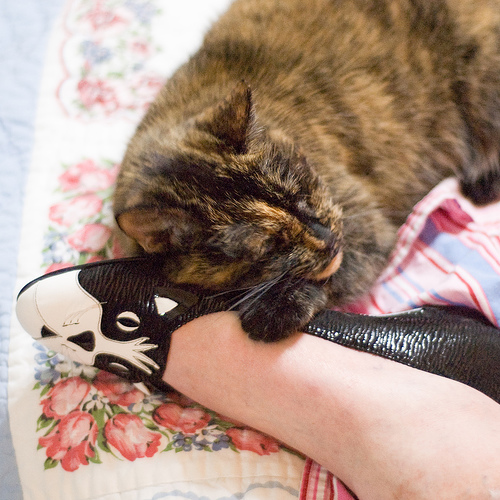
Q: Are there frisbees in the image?
A: No, there are no frisbees.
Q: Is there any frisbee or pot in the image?
A: No, there are no frisbees or pots.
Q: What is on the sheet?
A: The roses are on the sheet.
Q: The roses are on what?
A: The roses are on the bed sheet.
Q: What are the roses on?
A: The roses are on the bed sheet.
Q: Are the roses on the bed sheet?
A: Yes, the roses are on the bed sheet.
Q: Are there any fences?
A: No, there are no fences.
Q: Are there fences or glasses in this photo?
A: No, there are no fences or glasses.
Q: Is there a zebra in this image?
A: No, there are no zebras.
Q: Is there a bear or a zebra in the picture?
A: No, there are no zebras or bears.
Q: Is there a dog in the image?
A: No, there are no dogs.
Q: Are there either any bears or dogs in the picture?
A: No, there are no dogs or bears.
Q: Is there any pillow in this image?
A: No, there are no pillows.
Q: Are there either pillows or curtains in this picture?
A: No, there are no pillows or curtains.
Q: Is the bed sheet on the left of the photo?
A: Yes, the bed sheet is on the left of the image.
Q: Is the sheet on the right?
A: No, the sheet is on the left of the image.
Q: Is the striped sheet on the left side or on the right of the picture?
A: The bed sheet is on the left of the image.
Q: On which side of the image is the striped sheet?
A: The bed sheet is on the left of the image.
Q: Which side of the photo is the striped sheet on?
A: The bed sheet is on the left of the image.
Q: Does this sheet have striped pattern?
A: Yes, the sheet is striped.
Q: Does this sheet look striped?
A: Yes, the sheet is striped.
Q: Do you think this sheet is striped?
A: Yes, the sheet is striped.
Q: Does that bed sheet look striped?
A: Yes, the bed sheet is striped.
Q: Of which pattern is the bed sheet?
A: The bed sheet is striped.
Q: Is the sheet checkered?
A: No, the sheet is striped.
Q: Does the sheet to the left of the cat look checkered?
A: No, the bed sheet is striped.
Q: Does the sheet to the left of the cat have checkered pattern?
A: No, the bed sheet is striped.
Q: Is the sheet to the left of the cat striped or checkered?
A: The bed sheet is striped.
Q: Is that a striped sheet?
A: Yes, that is a striped sheet.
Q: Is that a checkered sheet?
A: No, that is a striped sheet.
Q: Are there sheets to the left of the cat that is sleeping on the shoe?
A: Yes, there is a sheet to the left of the cat.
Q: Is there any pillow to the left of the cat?
A: No, there is a sheet to the left of the cat.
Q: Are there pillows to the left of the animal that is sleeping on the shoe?
A: No, there is a sheet to the left of the cat.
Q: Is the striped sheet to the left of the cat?
A: Yes, the sheet is to the left of the cat.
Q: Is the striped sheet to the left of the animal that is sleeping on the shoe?
A: Yes, the sheet is to the left of the cat.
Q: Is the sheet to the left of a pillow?
A: No, the sheet is to the left of the cat.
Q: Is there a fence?
A: No, there are no fences.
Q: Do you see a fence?
A: No, there are no fences.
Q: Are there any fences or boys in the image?
A: No, there are no fences or boys.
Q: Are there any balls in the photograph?
A: No, there are no balls.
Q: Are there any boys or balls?
A: No, there are no balls or boys.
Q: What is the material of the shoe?
A: The shoe is made of leather.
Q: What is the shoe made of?
A: The shoe is made of leather.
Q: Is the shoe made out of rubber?
A: No, the shoe is made of leather.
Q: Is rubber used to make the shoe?
A: No, the shoe is made of leather.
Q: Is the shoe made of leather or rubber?
A: The shoe is made of leather.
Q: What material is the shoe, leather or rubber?
A: The shoe is made of leather.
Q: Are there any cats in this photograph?
A: Yes, there is a cat.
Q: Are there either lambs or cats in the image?
A: Yes, there is a cat.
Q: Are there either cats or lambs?
A: Yes, there is a cat.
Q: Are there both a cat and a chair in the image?
A: No, there is a cat but no chairs.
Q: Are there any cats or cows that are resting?
A: Yes, the cat is resting.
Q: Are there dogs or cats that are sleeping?
A: Yes, the cat is sleeping.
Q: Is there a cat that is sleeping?
A: Yes, there is a cat that is sleeping.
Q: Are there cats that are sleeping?
A: Yes, there is a cat that is sleeping.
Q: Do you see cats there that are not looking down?
A: Yes, there is a cat that is sleeping .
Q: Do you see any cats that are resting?
A: Yes, there is a cat that is resting.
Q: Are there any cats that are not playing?
A: Yes, there is a cat that is resting.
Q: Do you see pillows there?
A: No, there are no pillows.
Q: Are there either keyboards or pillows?
A: No, there are no pillows or keyboards.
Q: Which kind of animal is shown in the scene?
A: The animal is a cat.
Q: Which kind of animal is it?
A: The animal is a cat.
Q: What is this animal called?
A: That is a cat.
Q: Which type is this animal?
A: That is a cat.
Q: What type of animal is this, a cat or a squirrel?
A: That is a cat.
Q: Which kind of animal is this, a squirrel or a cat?
A: That is a cat.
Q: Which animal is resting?
A: The animal is a cat.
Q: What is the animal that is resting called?
A: The animal is a cat.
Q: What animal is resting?
A: The animal is a cat.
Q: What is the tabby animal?
A: The animal is a cat.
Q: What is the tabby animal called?
A: The animal is a cat.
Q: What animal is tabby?
A: The animal is a cat.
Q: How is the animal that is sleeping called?
A: The animal is a cat.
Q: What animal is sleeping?
A: The animal is a cat.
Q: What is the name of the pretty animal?
A: The animal is a cat.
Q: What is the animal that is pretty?
A: The animal is a cat.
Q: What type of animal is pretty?
A: The animal is a cat.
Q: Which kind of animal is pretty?
A: The animal is a cat.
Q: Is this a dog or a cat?
A: This is a cat.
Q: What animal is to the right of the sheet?
A: The animal is a cat.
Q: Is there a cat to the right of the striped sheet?
A: Yes, there is a cat to the right of the sheet.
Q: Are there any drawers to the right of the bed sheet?
A: No, there is a cat to the right of the bed sheet.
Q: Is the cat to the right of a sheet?
A: Yes, the cat is to the right of a sheet.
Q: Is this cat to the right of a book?
A: No, the cat is to the right of a sheet.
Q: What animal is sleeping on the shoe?
A: The cat is sleeping on the shoe.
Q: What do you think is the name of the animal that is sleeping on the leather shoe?
A: The animal is a cat.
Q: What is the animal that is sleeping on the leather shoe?
A: The animal is a cat.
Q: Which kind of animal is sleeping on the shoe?
A: The animal is a cat.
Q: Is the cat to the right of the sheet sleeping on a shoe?
A: Yes, the cat is sleeping on a shoe.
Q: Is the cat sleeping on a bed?
A: No, the cat is sleeping on a shoe.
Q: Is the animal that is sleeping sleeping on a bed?
A: No, the cat is sleeping on a shoe.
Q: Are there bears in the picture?
A: No, there are no bears.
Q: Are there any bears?
A: No, there are no bears.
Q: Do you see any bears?
A: No, there are no bears.